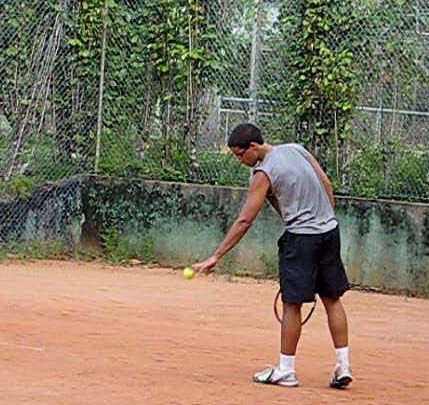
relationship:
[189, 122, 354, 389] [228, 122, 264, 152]
man with hair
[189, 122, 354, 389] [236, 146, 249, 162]
man wearing glasses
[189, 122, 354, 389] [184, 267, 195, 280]
man bouncing tennis ball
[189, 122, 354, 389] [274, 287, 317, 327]
man holding tennis racquet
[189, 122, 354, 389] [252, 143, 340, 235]
man wearing pullover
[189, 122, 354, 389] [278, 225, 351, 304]
man wearing shorts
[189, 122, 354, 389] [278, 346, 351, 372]
man wearing socks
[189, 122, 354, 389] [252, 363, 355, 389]
man wearing tennis shoes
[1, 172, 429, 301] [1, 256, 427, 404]
wall behind tennis court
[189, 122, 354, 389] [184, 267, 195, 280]
man serving tennis ball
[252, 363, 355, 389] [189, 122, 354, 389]
tennis shoes on man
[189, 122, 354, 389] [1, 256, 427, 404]
man on tennis court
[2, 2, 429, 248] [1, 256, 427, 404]
fence surrounding tennis court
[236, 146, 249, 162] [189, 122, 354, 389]
glasses on man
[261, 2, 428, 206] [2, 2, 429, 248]
trees behind fence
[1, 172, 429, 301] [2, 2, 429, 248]
wall holding fence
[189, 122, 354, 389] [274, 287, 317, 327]
man holds tennis racquet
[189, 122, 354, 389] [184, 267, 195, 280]
man dribbles tennis ball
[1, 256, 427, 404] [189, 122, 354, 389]
tennis court underneath man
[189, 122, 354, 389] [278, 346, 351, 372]
man wears socks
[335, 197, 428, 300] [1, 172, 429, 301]
algae on wall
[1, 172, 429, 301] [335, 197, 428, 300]
wall with algae